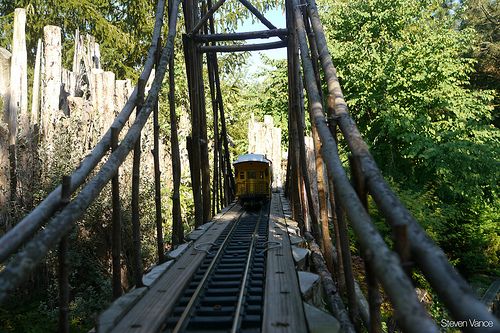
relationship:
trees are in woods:
[327, 25, 411, 74] [224, 93, 281, 153]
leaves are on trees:
[76, 10, 106, 25] [327, 25, 411, 74]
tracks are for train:
[227, 214, 269, 238] [229, 149, 273, 205]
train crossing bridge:
[229, 149, 273, 205] [169, 232, 280, 282]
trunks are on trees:
[301, 204, 331, 233] [327, 25, 411, 74]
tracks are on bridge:
[227, 214, 269, 238] [169, 232, 280, 282]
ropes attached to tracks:
[202, 73, 230, 116] [227, 214, 269, 238]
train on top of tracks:
[229, 149, 273, 205] [227, 214, 269, 238]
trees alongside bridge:
[327, 25, 411, 74] [169, 232, 280, 282]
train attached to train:
[230, 152, 274, 202] [229, 149, 273, 205]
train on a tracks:
[229, 149, 273, 205] [227, 214, 269, 238]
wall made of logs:
[80, 68, 132, 113] [69, 154, 145, 216]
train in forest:
[229, 149, 273, 205] [245, 17, 371, 73]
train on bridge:
[230, 152, 274, 202] [169, 232, 280, 282]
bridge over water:
[169, 232, 280, 282] [318, 296, 339, 308]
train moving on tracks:
[229, 149, 273, 205] [227, 214, 269, 238]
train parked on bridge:
[229, 149, 273, 205] [169, 232, 280, 282]